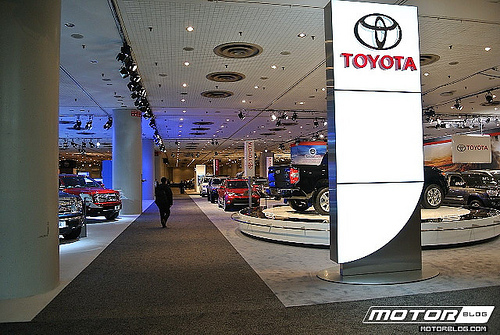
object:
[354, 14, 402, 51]
drawing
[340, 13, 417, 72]
logo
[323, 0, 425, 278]
sign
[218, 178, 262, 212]
car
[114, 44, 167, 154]
lights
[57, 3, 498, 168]
roof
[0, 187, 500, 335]
carpet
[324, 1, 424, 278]
board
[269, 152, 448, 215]
truck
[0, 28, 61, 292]
truck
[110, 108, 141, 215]
pillar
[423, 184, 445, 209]
front tire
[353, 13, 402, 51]
symbol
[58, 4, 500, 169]
ceiling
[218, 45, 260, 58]
air vent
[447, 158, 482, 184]
ground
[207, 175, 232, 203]
cars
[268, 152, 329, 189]
truckbed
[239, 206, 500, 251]
platform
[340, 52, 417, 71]
words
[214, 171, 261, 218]
blue sky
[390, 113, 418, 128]
ground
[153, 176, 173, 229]
man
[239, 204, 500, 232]
rail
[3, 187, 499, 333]
floor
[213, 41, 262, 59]
vent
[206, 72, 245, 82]
vent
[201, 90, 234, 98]
vent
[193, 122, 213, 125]
vent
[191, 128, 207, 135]
vent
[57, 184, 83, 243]
truck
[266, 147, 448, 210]
truck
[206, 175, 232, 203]
suv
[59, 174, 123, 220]
suv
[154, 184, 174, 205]
suit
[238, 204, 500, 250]
pedestal